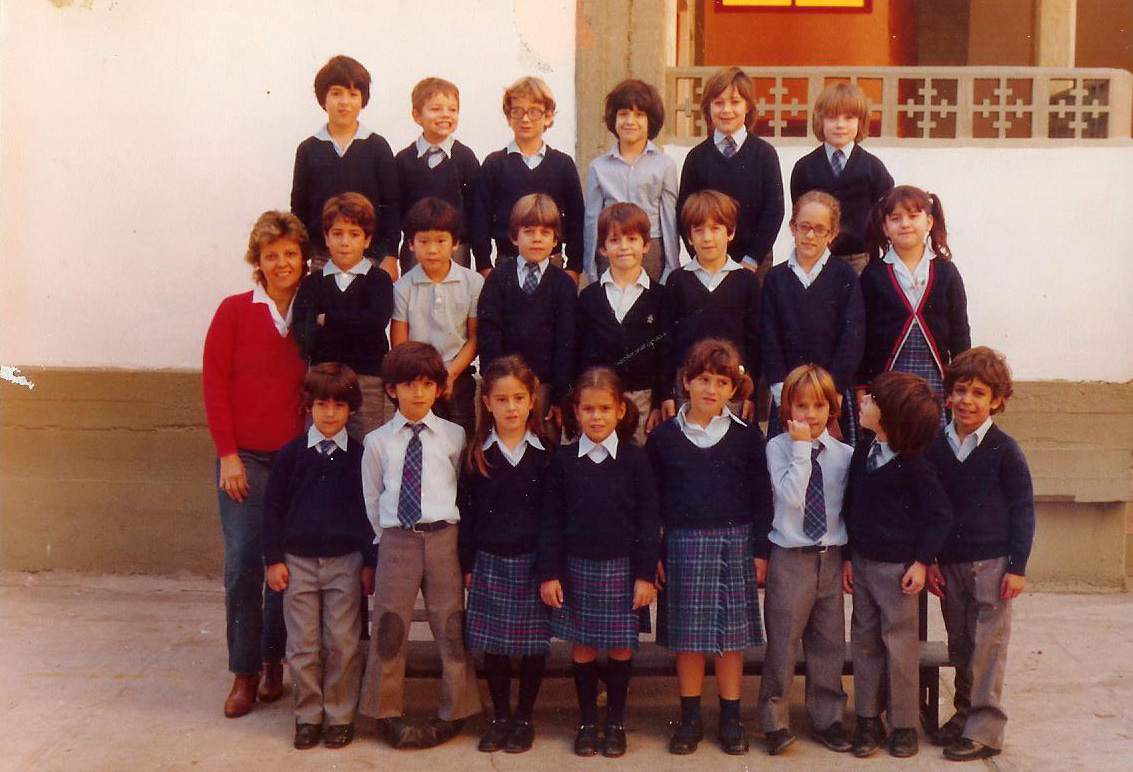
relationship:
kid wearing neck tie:
[755, 362, 854, 756] [801, 423, 843, 544]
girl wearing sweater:
[461, 348, 548, 747] [461, 431, 548, 563]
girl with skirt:
[653, 348, 771, 768] [653, 513, 766, 655]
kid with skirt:
[533, 367, 660, 758] [571, 549, 634, 655]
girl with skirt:
[457, 354, 556, 754] [464, 552, 551, 655]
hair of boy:
[601, 83, 670, 141] [580, 76, 678, 263]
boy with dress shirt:
[580, 76, 678, 263] [580, 148, 670, 264]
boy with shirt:
[393, 197, 486, 376] [393, 257, 486, 362]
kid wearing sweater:
[842, 371, 954, 758] [847, 434, 939, 574]